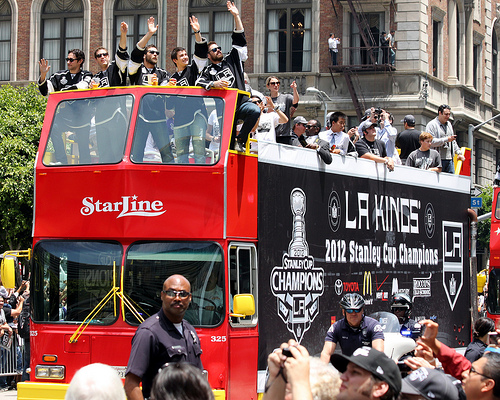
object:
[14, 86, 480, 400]
bus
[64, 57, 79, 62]
sunglasses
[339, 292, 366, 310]
helmet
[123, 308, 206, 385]
shirt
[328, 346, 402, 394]
cap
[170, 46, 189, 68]
head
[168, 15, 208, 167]
man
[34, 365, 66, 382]
headlight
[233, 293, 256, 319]
mirror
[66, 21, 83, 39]
curtain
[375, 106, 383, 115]
camera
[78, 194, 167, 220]
logo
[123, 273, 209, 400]
man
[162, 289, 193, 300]
glasses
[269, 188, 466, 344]
sign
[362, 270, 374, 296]
logo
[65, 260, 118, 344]
windshield wiper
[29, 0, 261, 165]
hockey team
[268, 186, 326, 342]
logo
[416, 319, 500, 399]
spectators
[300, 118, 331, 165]
people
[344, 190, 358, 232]
words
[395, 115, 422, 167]
man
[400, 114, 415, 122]
hat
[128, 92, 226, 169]
window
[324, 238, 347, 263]
"2012"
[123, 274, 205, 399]
policeman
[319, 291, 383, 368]
policeman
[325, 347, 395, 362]
bicycle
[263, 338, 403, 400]
person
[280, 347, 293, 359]
camera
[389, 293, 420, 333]
policeman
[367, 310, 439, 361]
motorcycle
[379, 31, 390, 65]
people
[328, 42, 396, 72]
balcony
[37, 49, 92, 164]
man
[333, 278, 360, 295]
toyota advertisement